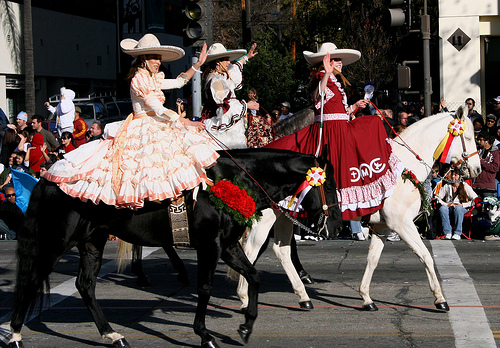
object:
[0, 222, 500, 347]
road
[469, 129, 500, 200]
spectators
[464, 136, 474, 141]
eye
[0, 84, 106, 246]
crowd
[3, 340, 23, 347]
hoof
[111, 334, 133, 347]
hoof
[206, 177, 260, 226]
decoration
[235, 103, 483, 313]
horse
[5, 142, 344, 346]
horse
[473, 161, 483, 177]
nose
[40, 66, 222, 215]
dress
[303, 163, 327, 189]
flower decoration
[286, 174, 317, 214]
horse bridle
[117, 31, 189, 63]
sombrero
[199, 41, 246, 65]
sombrero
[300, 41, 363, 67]
sombrero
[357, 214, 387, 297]
leg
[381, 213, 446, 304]
leg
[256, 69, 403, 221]
mexican dress.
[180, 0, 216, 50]
traffic light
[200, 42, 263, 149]
woman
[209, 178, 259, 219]
flowers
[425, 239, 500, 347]
line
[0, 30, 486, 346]
parade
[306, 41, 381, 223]
rider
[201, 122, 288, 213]
reign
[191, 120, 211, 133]
hand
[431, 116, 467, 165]
bridle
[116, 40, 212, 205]
person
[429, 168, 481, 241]
person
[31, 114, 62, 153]
person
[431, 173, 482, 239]
chair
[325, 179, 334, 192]
right eye